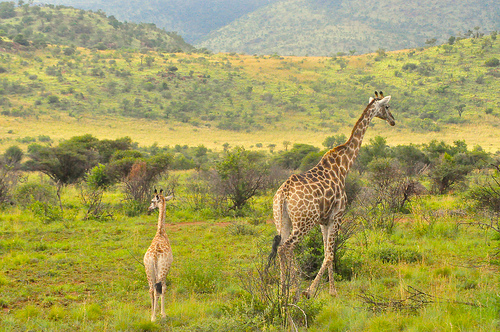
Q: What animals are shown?
A: Giraffes.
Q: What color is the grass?
A: Green.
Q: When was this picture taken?
A: Daytime.